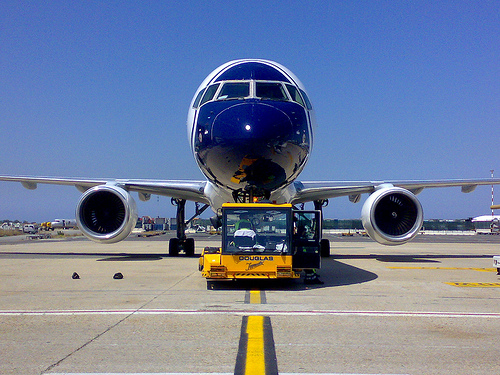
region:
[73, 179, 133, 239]
the large engine of the plane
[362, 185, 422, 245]
the large engine of the plane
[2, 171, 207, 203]
the long wing of the plane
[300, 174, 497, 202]
the long wing of the plane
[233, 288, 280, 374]
the black and yellow stripe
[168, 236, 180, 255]
the large black rubber wheel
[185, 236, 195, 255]
the long wing of the plane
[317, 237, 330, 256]
the long wing of the plane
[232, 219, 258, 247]
the person in the vehicle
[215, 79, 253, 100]
the window of the plane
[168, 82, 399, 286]
this is a plane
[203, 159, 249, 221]
the plane is commercial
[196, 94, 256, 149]
the plane is large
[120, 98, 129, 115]
there are no clouds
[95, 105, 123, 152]
the sky is very clear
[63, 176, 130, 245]
this is a jet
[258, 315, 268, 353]
this is a large line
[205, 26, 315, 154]
this is a window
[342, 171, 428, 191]
this is a wing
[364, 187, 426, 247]
Large white colored jet engine.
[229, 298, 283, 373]
Traffice markings on a landing field.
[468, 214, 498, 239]
A white plane hanger is on the right side.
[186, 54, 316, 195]
The blue front side of an airplane.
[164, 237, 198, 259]
The rear landing wheels of a large airplane.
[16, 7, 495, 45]
A blue cloudless sky.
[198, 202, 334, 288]
A yellow vehicle pulling a large airplane.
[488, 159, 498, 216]
A radio antennae on an airplane field.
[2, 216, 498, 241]
An horizon connecting the sky with an airplane field.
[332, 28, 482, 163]
A blue cloudless sky.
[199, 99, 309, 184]
blue nose on the plane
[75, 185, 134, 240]
an engine on the wing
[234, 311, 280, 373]
yellow and black stripes on the concrete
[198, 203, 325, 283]
a yellow plane cart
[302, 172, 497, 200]
wing of the plane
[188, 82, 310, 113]
windshield on the plane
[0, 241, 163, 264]
shadows on the concrete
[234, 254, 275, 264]
brand name on the vehicle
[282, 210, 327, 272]
cart door is open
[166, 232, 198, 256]
wheels on the landing gear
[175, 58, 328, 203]
front of a plane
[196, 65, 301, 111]
window of a plane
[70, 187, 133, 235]
turbine of a plane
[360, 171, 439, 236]
turbine of a plane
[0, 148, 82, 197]
wing of a plane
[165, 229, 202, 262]
wheel of a plane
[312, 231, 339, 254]
wheel of a plane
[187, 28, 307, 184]
cockpit of a plane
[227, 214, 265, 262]
person sitting in vehicle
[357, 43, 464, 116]
clear blue sky with no cloud